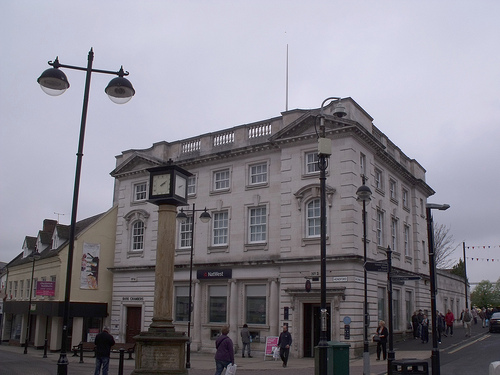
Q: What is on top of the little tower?
A: A clock.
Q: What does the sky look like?
A: Overcast.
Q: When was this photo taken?
A: During the daytime.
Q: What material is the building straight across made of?
A: Stone.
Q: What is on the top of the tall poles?
A: Street lights.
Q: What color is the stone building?
A: White.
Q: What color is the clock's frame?
A: Black.